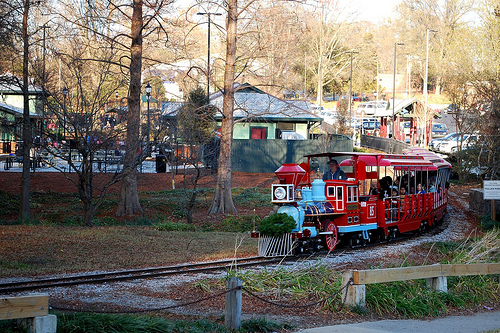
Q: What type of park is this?
A: An amusement park.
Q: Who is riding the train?
A: Children.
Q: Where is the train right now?
A: Coming around the corner.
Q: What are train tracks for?
A: To keep the train on track..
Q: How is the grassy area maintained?
A: With a fence.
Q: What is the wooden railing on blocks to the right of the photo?
A: Part of the fence.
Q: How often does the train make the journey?
A: Every two hours.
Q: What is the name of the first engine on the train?
A: Locomotive.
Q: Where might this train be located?
A: Theme park.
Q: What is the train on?
A: Tracks.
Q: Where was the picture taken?
A: In a park.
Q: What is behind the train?
A: Trees.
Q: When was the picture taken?
A: During the daytime.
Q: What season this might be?
A: Autumn.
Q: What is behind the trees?
A: Buildings.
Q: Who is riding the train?
A: Children.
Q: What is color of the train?
A: Red and blue.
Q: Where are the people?
A: In the train.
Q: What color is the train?
A: Red.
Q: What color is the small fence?
A: Light brown.